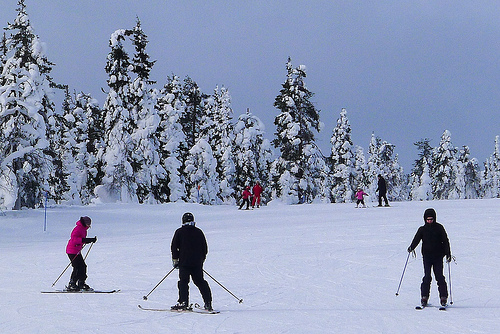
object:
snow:
[267, 218, 356, 330]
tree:
[329, 106, 355, 202]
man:
[169, 212, 215, 313]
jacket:
[171, 222, 209, 264]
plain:
[1, 199, 500, 333]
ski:
[438, 297, 448, 310]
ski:
[193, 303, 221, 315]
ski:
[136, 300, 194, 313]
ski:
[41, 289, 122, 295]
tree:
[96, 17, 158, 204]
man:
[252, 180, 265, 208]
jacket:
[252, 185, 263, 196]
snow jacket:
[65, 220, 89, 255]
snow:
[1, 212, 45, 317]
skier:
[395, 208, 459, 312]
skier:
[40, 215, 120, 293]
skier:
[375, 174, 389, 207]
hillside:
[2, 199, 500, 331]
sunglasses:
[427, 218, 436, 221]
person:
[406, 207, 452, 311]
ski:
[415, 294, 431, 310]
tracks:
[133, 315, 206, 332]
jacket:
[406, 222, 451, 259]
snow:
[296, 204, 360, 238]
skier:
[237, 186, 252, 210]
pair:
[238, 181, 265, 211]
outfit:
[252, 181, 263, 211]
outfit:
[241, 186, 252, 199]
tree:
[269, 55, 325, 204]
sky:
[2, 1, 499, 167]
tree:
[232, 105, 276, 206]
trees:
[0, 0, 71, 207]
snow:
[286, 122, 300, 139]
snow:
[411, 155, 432, 201]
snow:
[163, 157, 183, 172]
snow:
[100, 144, 121, 175]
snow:
[21, 85, 44, 112]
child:
[354, 188, 369, 209]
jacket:
[354, 191, 369, 200]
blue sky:
[172, 11, 478, 48]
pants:
[69, 253, 88, 283]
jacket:
[65, 220, 89, 255]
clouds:
[157, 16, 204, 39]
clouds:
[163, 24, 239, 62]